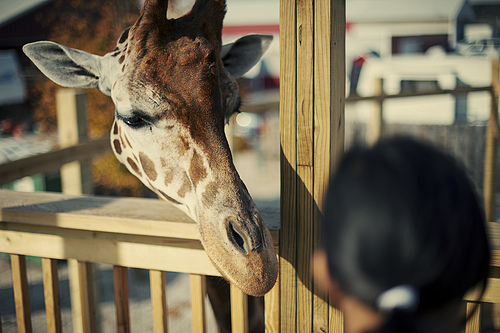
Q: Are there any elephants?
A: No, there are no elephants.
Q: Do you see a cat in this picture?
A: No, there are no cats.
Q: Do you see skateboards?
A: No, there are no skateboards.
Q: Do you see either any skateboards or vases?
A: No, there are no skateboards or vases.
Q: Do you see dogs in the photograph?
A: No, there are no dogs.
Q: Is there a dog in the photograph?
A: No, there are no dogs.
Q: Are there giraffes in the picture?
A: Yes, there is a giraffe.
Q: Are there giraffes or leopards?
A: Yes, there is a giraffe.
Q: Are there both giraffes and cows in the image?
A: No, there is a giraffe but no cows.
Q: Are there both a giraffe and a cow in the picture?
A: No, there is a giraffe but no cows.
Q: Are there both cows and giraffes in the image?
A: No, there is a giraffe but no cows.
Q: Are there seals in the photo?
A: No, there are no seals.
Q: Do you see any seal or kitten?
A: No, there are no seals or kittens.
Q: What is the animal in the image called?
A: The animal is a giraffe.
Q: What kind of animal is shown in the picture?
A: The animal is a giraffe.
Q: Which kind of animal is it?
A: The animal is a giraffe.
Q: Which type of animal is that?
A: That is a giraffe.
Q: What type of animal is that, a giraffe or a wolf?
A: That is a giraffe.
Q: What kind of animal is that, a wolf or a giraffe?
A: That is a giraffe.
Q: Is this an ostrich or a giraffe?
A: This is a giraffe.